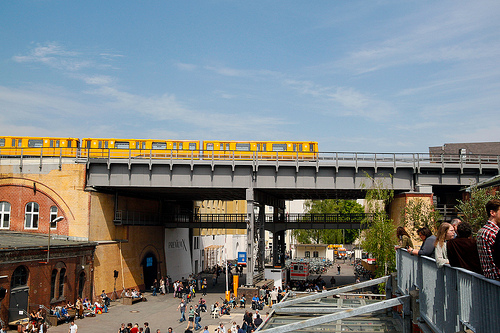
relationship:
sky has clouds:
[1, 1, 499, 138] [1, 41, 495, 137]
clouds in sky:
[1, 41, 495, 137] [1, 1, 499, 138]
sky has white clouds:
[1, 1, 499, 138] [1, 41, 495, 137]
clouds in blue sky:
[1, 41, 495, 137] [1, 1, 499, 138]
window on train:
[111, 139, 130, 152] [0, 128, 321, 166]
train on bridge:
[0, 128, 321, 166] [83, 153, 404, 201]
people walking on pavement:
[19, 265, 352, 331] [74, 279, 238, 331]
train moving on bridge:
[0, 128, 321, 166] [83, 153, 404, 201]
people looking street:
[19, 265, 352, 331] [74, 279, 238, 331]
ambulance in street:
[287, 259, 315, 283] [279, 252, 358, 292]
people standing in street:
[19, 265, 352, 331] [74, 279, 238, 331]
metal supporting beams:
[244, 188, 273, 281] [83, 153, 404, 201]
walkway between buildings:
[115, 203, 388, 229] [5, 187, 443, 262]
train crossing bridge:
[0, 128, 321, 166] [83, 153, 404, 201]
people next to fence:
[389, 221, 436, 252] [393, 244, 439, 323]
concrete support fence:
[266, 261, 427, 327] [393, 244, 439, 323]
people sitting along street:
[19, 265, 352, 331] [74, 279, 238, 331]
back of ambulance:
[292, 260, 303, 276] [287, 259, 315, 283]